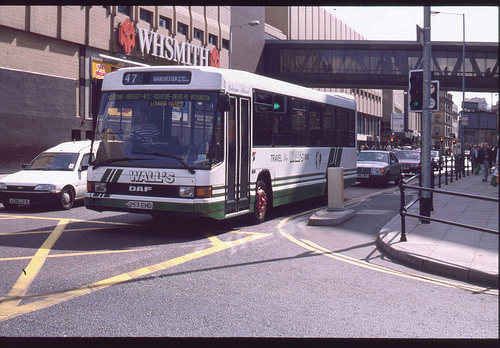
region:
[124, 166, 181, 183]
The word WALL'S on the front of the bus.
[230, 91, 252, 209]
Double doors on side of bus.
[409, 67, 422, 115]
Traffic light to the right of bus.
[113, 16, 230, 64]
White business name including red design.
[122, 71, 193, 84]
Marquee display including number of bus and destination.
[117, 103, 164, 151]
The man driving the bus.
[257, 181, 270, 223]
Red hub cap of bus wheel.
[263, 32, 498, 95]
Walking bridge connecting buildings.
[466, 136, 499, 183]
People walking on the sidewalk on the right.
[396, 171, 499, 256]
Black iron gate on sidewalk.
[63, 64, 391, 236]
Green and white bus on street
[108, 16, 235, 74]
White lettering on building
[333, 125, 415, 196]
Grey car driving on street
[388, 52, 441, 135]
Street light showing green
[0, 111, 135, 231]
White car parked on street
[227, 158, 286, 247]
Black tire with red rim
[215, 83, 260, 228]
Glass bus door on bus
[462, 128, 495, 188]
Group of people walking down the street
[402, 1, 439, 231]
Metal pole with traffic lights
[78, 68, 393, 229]
Bus driving down the street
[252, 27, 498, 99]
an overhead bridge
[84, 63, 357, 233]
bus at intersection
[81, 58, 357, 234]
green and white bus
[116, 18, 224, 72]
sign for bookstore and stationary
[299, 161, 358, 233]
a concrete barrier in the street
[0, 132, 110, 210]
a white vehicle beside the bus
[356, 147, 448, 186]
traffic behind the bus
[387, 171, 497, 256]
pedestrian restraint bars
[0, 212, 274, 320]
anti gridlock markings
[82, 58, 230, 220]
bus number 47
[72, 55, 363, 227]
city bus driving on a busy city street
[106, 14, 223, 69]
a sign for a business on a building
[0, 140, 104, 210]
a white car next to the bus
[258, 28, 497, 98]
an enclosed walkway over the road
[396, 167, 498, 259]
a black metal barrier at the sidewalk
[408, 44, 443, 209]
a traffic signal on the corner of the street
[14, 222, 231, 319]
several yellow lines painted in the street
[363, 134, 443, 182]
heavy traffic down the street behind the bus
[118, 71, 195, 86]
the number and location the bus is headed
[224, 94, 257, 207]
double doors on the front of the bus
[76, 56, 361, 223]
White and green bus moving in traffic.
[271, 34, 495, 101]
Overhead walkway above street.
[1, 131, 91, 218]
White car next to bus.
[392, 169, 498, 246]
Metal railing along sidewalk.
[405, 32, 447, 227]
Traffic light on corner of street.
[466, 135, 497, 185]
People walking down sidewalk.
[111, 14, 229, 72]
Name of company on outside wall.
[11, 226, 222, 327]
Yellow markings on the street.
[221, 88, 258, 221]
Door to bus.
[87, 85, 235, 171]
Front window of bus.